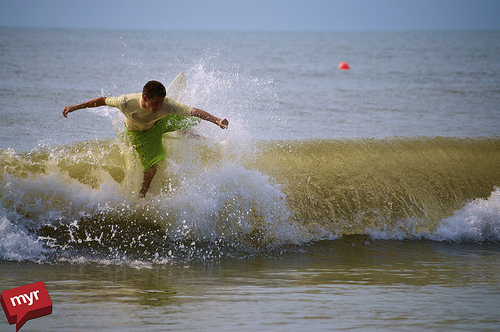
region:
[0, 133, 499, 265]
A wave crashing down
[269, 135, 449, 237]
A wave crest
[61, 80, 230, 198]
A person being hit by a wave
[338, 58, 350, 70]
An orange floating item in the water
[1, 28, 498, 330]
The ocean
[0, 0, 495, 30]
A clear blue sky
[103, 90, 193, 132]
A wet yellow shirt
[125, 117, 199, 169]
A pair of green shorts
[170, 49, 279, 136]
A splash of water in the air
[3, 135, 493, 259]
A wave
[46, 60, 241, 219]
a surfer in the ocean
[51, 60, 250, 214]
surfer is bend forward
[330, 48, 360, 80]
an orange ball in the ocean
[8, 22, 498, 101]
waters of ocean are calm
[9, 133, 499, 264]
a wave rolling in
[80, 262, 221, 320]
reflection of a person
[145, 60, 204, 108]
a white surfboard behind a man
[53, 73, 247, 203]
surfer has extended arms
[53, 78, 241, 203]
surfer wears yellow shirt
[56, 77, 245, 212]
surfer has green shorts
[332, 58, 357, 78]
red buoy floating in the ocean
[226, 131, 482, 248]
round wave crashing at the ocean shoreline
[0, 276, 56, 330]
red attribution logo on photo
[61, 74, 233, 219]
man standing on one leg in a wave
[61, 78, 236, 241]
man with green shorts and white shirt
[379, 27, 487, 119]
waves in the gray ocean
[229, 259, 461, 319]
calm water in front of crashing wave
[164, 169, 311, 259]
foam from a round crashing wave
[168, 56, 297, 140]
spray from man's foot in a curved wave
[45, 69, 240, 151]
arms held out to the sides for balance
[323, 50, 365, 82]
ball in ocean water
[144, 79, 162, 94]
black hair on head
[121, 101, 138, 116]
white shirt on man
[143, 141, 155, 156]
green shorts on man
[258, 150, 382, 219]
big wave in water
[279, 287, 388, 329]
small waves in water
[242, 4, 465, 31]
clear skies in the sky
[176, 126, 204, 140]
boys foot in water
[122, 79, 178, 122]
boys face looking down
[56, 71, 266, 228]
boy playing water sport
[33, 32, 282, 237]
The boy is in the water.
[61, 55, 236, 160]
The boy's arms are outstretched.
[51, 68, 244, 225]
The boy is wearing a shirt.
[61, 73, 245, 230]
The boy is wearing shorts.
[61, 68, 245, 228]
The boy's shirt is yellow.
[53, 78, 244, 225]
The boy's shorts are green.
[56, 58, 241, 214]
The boy has short hair.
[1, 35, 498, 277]
The water is splashing.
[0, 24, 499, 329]
The water is wavy.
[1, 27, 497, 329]
The water is ripply.